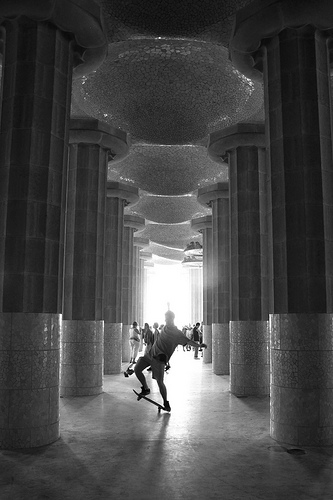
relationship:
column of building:
[0, 2, 77, 457] [1, 1, 332, 496]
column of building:
[57, 141, 111, 397] [1, 1, 332, 496]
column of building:
[101, 199, 123, 379] [1, 1, 332, 496]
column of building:
[253, 17, 332, 444] [1, 1, 332, 496]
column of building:
[222, 147, 272, 399] [1, 1, 332, 496]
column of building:
[216, 196, 228, 376] [1, 1, 332, 496]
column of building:
[199, 223, 214, 361] [1, 1, 332, 496]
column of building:
[122, 231, 132, 373] [1, 1, 332, 496]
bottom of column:
[0, 311, 63, 456] [0, 2, 77, 457]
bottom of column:
[61, 320, 102, 399] [57, 141, 111, 397]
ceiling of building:
[49, 2, 264, 261] [1, 1, 332, 496]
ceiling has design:
[49, 2, 264, 261] [72, 34, 255, 136]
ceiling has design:
[49, 2, 264, 261] [107, 139, 230, 195]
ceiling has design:
[49, 2, 264, 261] [119, 191, 211, 227]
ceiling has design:
[49, 2, 264, 261] [138, 221, 200, 246]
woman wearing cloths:
[125, 320, 144, 372] [129, 330, 146, 360]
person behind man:
[194, 323, 205, 362] [135, 309, 208, 413]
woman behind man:
[125, 320, 144, 372] [135, 309, 208, 413]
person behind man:
[141, 324, 153, 345] [135, 309, 208, 413]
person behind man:
[148, 322, 165, 336] [135, 309, 208, 413]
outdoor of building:
[144, 249, 191, 332] [1, 1, 332, 496]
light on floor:
[125, 323, 205, 430] [2, 334, 328, 498]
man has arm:
[135, 309, 208, 413] [176, 333, 209, 352]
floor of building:
[2, 334, 328, 498] [1, 1, 332, 496]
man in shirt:
[135, 309, 208, 413] [147, 320, 186, 370]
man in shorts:
[135, 309, 208, 413] [137, 355, 163, 384]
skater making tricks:
[134, 308, 208, 412] [128, 384, 171, 416]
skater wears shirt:
[134, 309, 208, 411] [147, 324, 186, 360]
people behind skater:
[186, 324, 200, 342] [136, 308, 178, 410]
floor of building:
[2, 340, 327, 500] [1, 1, 332, 496]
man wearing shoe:
[137, 311, 203, 413] [164, 402, 171, 411]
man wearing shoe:
[137, 311, 203, 413] [139, 386, 147, 403]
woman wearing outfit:
[129, 321, 142, 363] [130, 327, 138, 361]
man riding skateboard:
[135, 309, 208, 413] [133, 390, 169, 411]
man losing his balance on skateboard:
[135, 309, 208, 413] [128, 387, 170, 414]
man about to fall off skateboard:
[135, 309, 208, 413] [131, 389, 167, 414]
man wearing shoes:
[135, 309, 208, 413] [138, 386, 169, 410]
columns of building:
[180, 21, 332, 485] [1, 1, 332, 496]